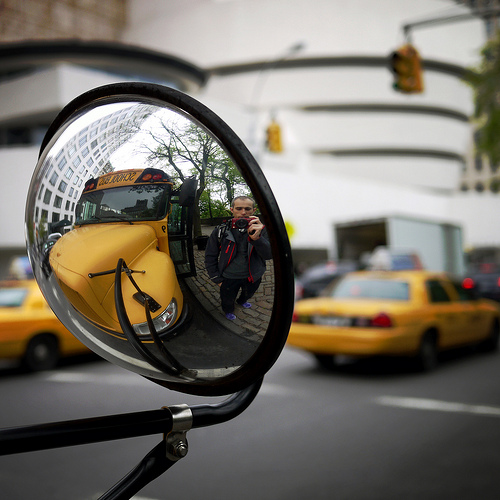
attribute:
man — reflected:
[207, 192, 269, 326]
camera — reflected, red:
[227, 218, 249, 239]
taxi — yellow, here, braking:
[281, 264, 499, 371]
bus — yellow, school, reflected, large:
[44, 164, 200, 338]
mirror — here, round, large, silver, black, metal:
[18, 85, 291, 393]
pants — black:
[220, 277, 267, 311]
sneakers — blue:
[224, 299, 260, 324]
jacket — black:
[207, 222, 273, 285]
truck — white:
[331, 214, 469, 278]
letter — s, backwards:
[129, 167, 141, 182]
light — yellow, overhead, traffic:
[392, 44, 420, 91]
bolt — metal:
[168, 436, 191, 459]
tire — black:
[27, 330, 64, 369]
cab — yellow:
[0, 271, 80, 370]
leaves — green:
[200, 175, 219, 217]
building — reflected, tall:
[48, 98, 153, 247]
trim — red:
[222, 240, 236, 258]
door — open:
[340, 216, 390, 270]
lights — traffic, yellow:
[259, 24, 446, 156]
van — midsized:
[306, 258, 362, 295]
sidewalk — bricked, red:
[180, 203, 277, 341]